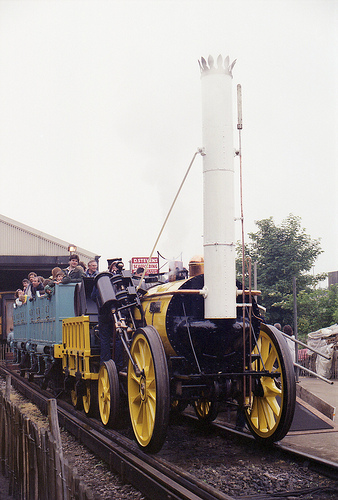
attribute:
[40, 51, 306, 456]
engine — steam, pulling, yellow, black, coal carrier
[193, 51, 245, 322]
stack — steam, white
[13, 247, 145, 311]
people — crowd, riding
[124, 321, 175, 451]
wheel — large, train, luxurious, black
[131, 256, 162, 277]
signage — shaped, white, red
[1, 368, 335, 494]
tracks — filled, railroad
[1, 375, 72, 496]
fence — picket, wooden, slatted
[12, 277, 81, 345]
bucket — passenger, blue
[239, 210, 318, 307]
tree — green, tall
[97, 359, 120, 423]
wheel — rear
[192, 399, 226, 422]
wheel — rear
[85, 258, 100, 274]
person — riding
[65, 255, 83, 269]
person — riding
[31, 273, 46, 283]
person — riding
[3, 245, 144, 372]
car — passenger, blue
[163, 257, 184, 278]
whistle — locomotive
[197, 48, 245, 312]
pipe — steam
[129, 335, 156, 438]
interior — yellow, luxurious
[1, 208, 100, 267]
roof — station's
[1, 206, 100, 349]
station — railway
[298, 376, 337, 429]
ramp — here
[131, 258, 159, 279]
sign — white, red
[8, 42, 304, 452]
train — open air